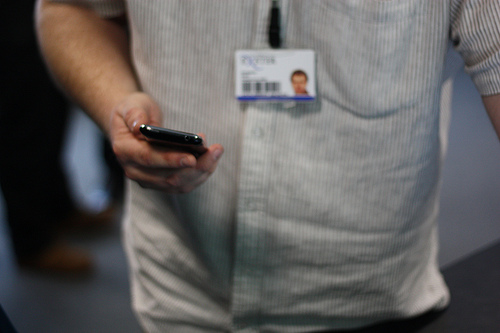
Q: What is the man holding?
A: A cellular phone.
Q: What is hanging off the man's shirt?
A: An employee badge.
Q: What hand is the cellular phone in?
A: The man's right.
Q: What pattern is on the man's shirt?
A: Stripes.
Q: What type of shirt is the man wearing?
A: A button up shirt.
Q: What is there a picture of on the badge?
A: A man.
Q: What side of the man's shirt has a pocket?
A: His left.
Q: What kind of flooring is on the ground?
A: Carpet.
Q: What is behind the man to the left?
A: Another person's legs.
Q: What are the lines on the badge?
A: A barcode.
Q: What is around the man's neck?
A: An ID badge.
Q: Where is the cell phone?
A: In a man's hand.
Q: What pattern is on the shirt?
A: Grey stripes.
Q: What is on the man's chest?
A: A shirt.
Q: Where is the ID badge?
A: Around the man's neck.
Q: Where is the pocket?
A: On his shirt.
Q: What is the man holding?
A: A cell phone.